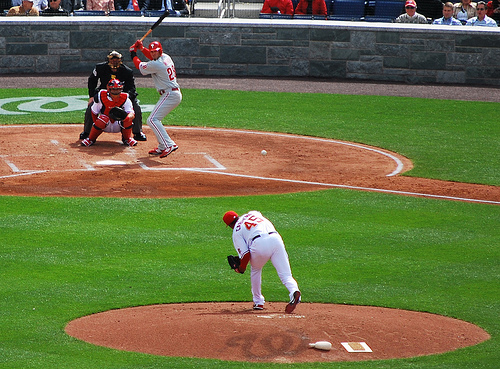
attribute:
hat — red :
[221, 203, 241, 216]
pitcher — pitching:
[222, 211, 303, 312]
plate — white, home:
[95, 157, 129, 166]